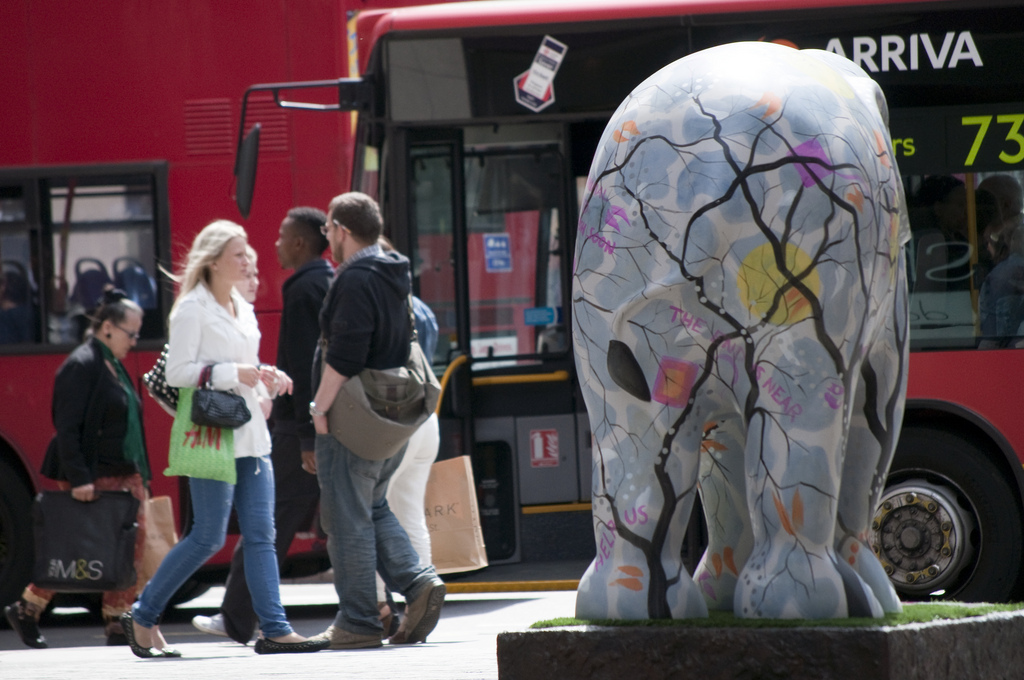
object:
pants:
[310, 384, 445, 630]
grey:
[312, 431, 425, 638]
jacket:
[161, 282, 271, 457]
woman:
[106, 219, 339, 659]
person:
[302, 191, 445, 650]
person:
[0, 290, 156, 650]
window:
[373, 131, 605, 379]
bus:
[328, 0, 1024, 604]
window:
[32, 185, 164, 344]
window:
[2, 184, 59, 356]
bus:
[0, 0, 487, 606]